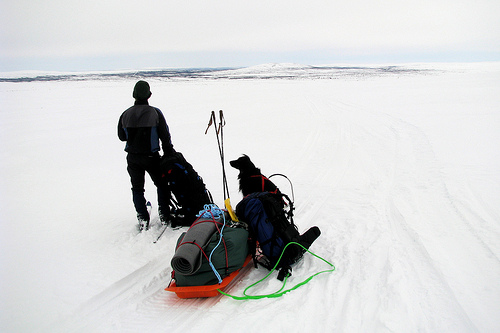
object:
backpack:
[160, 153, 213, 228]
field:
[4, 68, 496, 332]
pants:
[125, 153, 173, 222]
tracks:
[113, 269, 221, 332]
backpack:
[171, 219, 249, 287]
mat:
[169, 208, 230, 275]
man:
[116, 80, 175, 230]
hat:
[133, 80, 153, 100]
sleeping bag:
[171, 224, 249, 286]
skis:
[145, 201, 176, 244]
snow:
[1, 61, 500, 332]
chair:
[164, 255, 253, 299]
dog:
[229, 154, 285, 208]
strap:
[252, 175, 277, 194]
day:
[5, 0, 499, 333]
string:
[250, 265, 356, 305]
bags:
[171, 226, 249, 288]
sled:
[164, 239, 260, 300]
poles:
[210, 110, 231, 209]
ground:
[1, 67, 481, 322]